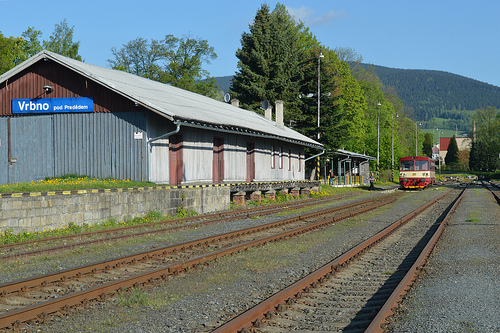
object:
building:
[1, 49, 324, 204]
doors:
[181, 130, 215, 184]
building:
[309, 148, 372, 187]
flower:
[46, 177, 48, 179]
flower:
[67, 180, 70, 182]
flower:
[95, 177, 98, 179]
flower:
[106, 180, 108, 181]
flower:
[30, 180, 34, 183]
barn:
[0, 51, 327, 186]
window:
[270, 144, 276, 169]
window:
[279, 145, 283, 169]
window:
[288, 145, 292, 171]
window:
[298, 151, 301, 171]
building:
[431, 120, 477, 169]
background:
[194, 60, 482, 181]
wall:
[1, 179, 231, 236]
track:
[1, 177, 373, 261]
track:
[209, 180, 469, 333]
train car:
[397, 156, 436, 189]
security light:
[317, 49, 325, 144]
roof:
[438, 135, 471, 150]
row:
[234, 4, 435, 170]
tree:
[231, 2, 306, 128]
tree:
[291, 56, 351, 172]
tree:
[321, 50, 364, 154]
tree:
[381, 100, 399, 170]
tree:
[399, 118, 417, 157]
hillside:
[193, 59, 498, 139]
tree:
[424, 111, 426, 121]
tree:
[457, 100, 460, 109]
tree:
[447, 88, 451, 95]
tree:
[427, 75, 430, 81]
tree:
[394, 78, 399, 84]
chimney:
[275, 99, 285, 125]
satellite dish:
[262, 100, 270, 110]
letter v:
[18, 101, 25, 110]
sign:
[11, 96, 93, 114]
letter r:
[24, 103, 29, 110]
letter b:
[29, 101, 37, 111]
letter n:
[36, 103, 43, 110]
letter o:
[42, 103, 49, 110]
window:
[399, 158, 415, 172]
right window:
[414, 158, 428, 171]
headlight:
[399, 174, 403, 176]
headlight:
[403, 173, 405, 176]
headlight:
[422, 173, 425, 177]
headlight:
[425, 173, 428, 176]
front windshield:
[399, 160, 429, 171]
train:
[399, 156, 437, 189]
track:
[8, 188, 405, 318]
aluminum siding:
[1, 114, 151, 188]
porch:
[230, 179, 317, 205]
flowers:
[28, 182, 38, 188]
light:
[42, 85, 54, 92]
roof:
[0, 49, 327, 150]